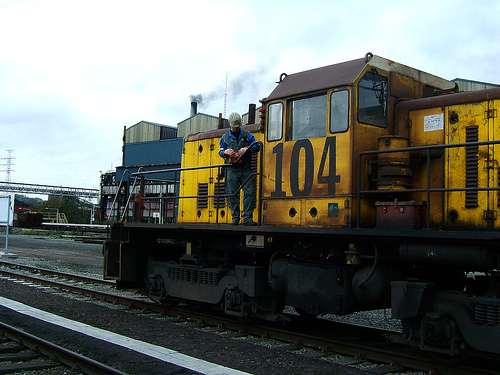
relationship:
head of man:
[229, 116, 244, 133] [221, 111, 262, 224]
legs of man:
[226, 168, 258, 225] [221, 111, 262, 224]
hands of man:
[226, 148, 247, 155] [221, 111, 262, 224]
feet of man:
[231, 214, 257, 225] [221, 111, 262, 224]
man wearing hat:
[221, 111, 262, 224] [230, 114, 241, 127]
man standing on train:
[221, 111, 262, 224] [108, 54, 499, 356]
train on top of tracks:
[108, 54, 499, 356] [4, 262, 500, 375]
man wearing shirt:
[221, 111, 262, 224] [218, 132, 260, 168]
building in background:
[99, 109, 215, 219] [5, 2, 180, 232]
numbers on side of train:
[271, 143, 341, 197] [108, 54, 499, 356]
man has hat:
[221, 111, 262, 224] [230, 114, 241, 127]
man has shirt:
[221, 111, 262, 224] [218, 132, 260, 168]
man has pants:
[221, 111, 262, 224] [226, 167, 254, 217]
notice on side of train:
[425, 115, 442, 130] [108, 54, 499, 356]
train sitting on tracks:
[108, 54, 499, 356] [4, 262, 500, 375]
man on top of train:
[221, 111, 262, 224] [108, 54, 499, 356]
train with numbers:
[108, 54, 499, 356] [271, 143, 341, 197]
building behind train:
[99, 109, 215, 219] [108, 54, 499, 356]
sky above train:
[1, 2, 495, 192] [108, 54, 499, 356]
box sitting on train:
[373, 200, 427, 228] [108, 54, 499, 356]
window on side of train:
[270, 77, 393, 137] [108, 54, 499, 356]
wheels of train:
[140, 270, 492, 348] [108, 54, 499, 356]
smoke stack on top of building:
[188, 98, 200, 115] [99, 109, 215, 219]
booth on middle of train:
[266, 59, 413, 220] [108, 54, 499, 356]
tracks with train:
[4, 262, 500, 375] [108, 54, 499, 356]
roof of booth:
[273, 55, 370, 92] [266, 59, 413, 220]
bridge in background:
[1, 178, 99, 199] [4, 3, 106, 242]